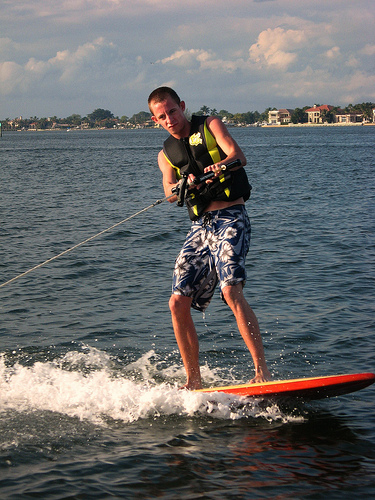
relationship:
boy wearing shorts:
[145, 85, 273, 393] [169, 209, 256, 306]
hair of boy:
[148, 86, 181, 115] [145, 85, 273, 393]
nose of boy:
[165, 112, 174, 124] [145, 85, 273, 393]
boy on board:
[148, 87, 272, 392] [190, 370, 372, 406]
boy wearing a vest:
[148, 87, 272, 392] [162, 114, 251, 220]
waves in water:
[13, 139, 288, 499] [273, 168, 359, 330]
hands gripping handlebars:
[139, 148, 268, 210] [166, 158, 235, 196]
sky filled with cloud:
[1, 2, 374, 103] [0, 0, 375, 110]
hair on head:
[148, 86, 181, 115] [135, 85, 194, 139]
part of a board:
[189, 374, 323, 410] [191, 371, 375, 396]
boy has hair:
[145, 85, 273, 393] [146, 84, 181, 115]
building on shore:
[333, 108, 373, 123] [5, 102, 374, 142]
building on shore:
[304, 103, 340, 122] [5, 102, 374, 142]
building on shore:
[267, 108, 293, 125] [5, 102, 374, 142]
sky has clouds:
[0, 0, 375, 103] [220, 22, 344, 86]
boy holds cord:
[145, 85, 273, 393] [3, 193, 176, 313]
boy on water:
[148, 87, 272, 392] [259, 149, 352, 265]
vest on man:
[162, 117, 238, 211] [129, 73, 284, 389]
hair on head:
[148, 86, 180, 114] [148, 86, 185, 134]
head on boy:
[148, 86, 185, 134] [148, 87, 272, 392]